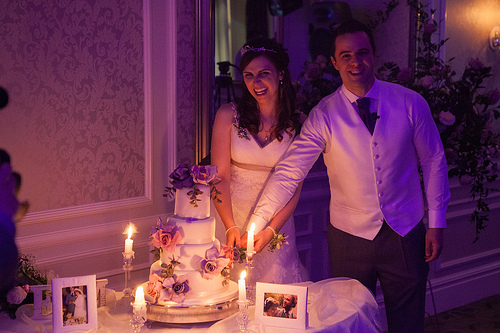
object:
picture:
[253, 279, 308, 330]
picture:
[50, 265, 99, 332]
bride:
[207, 37, 301, 270]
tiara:
[237, 40, 290, 67]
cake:
[148, 165, 240, 320]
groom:
[271, 17, 456, 293]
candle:
[116, 222, 146, 291]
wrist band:
[257, 223, 280, 241]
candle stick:
[119, 257, 141, 315]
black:
[359, 93, 381, 133]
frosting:
[175, 224, 222, 280]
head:
[330, 7, 392, 96]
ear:
[322, 48, 347, 76]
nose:
[345, 55, 366, 69]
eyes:
[358, 49, 371, 62]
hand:
[426, 224, 453, 279]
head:
[231, 39, 295, 120]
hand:
[220, 211, 244, 286]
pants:
[321, 220, 437, 333]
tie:
[352, 93, 380, 144]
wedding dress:
[213, 100, 325, 295]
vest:
[296, 104, 425, 249]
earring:
[277, 75, 290, 86]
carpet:
[414, 290, 498, 333]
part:
[463, 284, 499, 328]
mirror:
[403, 17, 498, 145]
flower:
[438, 110, 456, 139]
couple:
[203, 29, 427, 300]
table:
[44, 262, 372, 327]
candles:
[124, 274, 153, 331]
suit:
[289, 84, 453, 313]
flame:
[116, 223, 144, 243]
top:
[173, 173, 232, 222]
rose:
[146, 225, 184, 257]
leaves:
[159, 259, 171, 270]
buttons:
[370, 135, 390, 210]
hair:
[238, 42, 290, 149]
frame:
[246, 284, 309, 323]